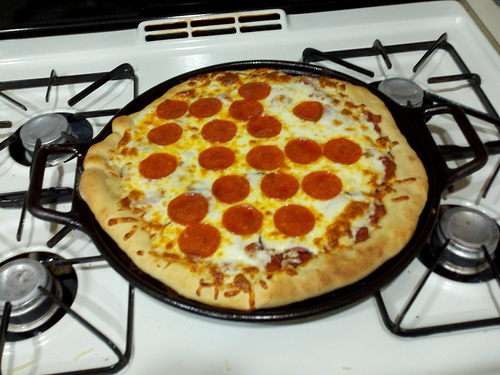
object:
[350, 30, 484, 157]
burner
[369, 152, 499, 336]
burner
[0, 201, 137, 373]
burner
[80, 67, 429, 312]
crust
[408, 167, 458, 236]
ground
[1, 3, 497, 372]
oven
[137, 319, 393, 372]
part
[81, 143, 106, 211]
puffy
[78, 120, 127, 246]
crust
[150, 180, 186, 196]
cheese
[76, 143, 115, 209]
pizza edge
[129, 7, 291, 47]
oven vent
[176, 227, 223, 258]
piece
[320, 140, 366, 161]
piece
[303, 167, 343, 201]
piece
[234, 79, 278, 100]
piece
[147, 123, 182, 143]
pepperoni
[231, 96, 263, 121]
pepperoni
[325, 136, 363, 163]
pepperoni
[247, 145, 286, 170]
pepperoni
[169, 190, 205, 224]
pepperoni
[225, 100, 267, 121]
toppings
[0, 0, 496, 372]
stove top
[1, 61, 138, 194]
burner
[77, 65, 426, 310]
pizza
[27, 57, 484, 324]
pan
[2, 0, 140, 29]
back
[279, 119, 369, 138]
cheese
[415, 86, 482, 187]
handle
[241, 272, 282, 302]
part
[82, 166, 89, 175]
edge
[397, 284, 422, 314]
part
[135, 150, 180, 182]
piece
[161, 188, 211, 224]
piece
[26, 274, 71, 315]
part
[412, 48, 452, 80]
part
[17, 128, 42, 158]
part